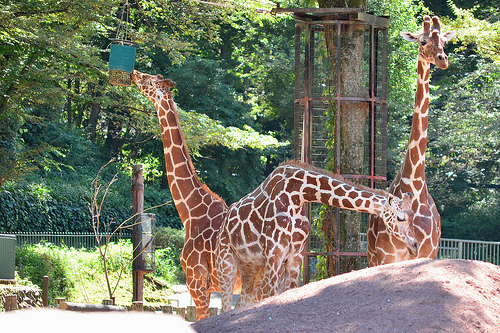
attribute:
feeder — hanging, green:
[107, 42, 138, 86]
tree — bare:
[88, 157, 175, 307]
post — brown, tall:
[129, 161, 146, 309]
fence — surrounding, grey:
[2, 225, 500, 332]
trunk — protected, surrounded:
[316, 0, 373, 278]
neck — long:
[295, 165, 389, 222]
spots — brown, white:
[236, 202, 299, 251]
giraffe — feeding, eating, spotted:
[129, 69, 266, 320]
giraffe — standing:
[366, 12, 455, 269]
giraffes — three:
[130, 12, 451, 323]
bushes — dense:
[14, 238, 180, 302]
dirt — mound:
[190, 258, 499, 332]